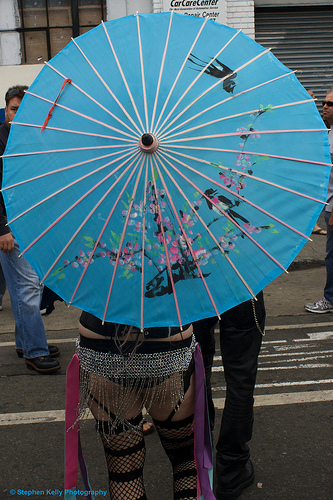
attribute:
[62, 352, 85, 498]
ribbon — colorful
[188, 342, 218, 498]
ribbon — colorful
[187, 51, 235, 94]
bird — black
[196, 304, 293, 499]
pants — jeans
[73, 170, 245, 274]
flower — pink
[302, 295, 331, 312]
shoe — white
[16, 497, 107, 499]
lettering — blue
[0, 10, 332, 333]
umbrella — blue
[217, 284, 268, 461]
pants — black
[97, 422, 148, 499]
stockings — fish net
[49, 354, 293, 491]
ribbons — colorful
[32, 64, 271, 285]
umbrella — blue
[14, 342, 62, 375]
shoes — black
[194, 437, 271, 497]
shoe — black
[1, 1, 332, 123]
building — white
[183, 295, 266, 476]
pants — black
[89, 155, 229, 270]
flower — white